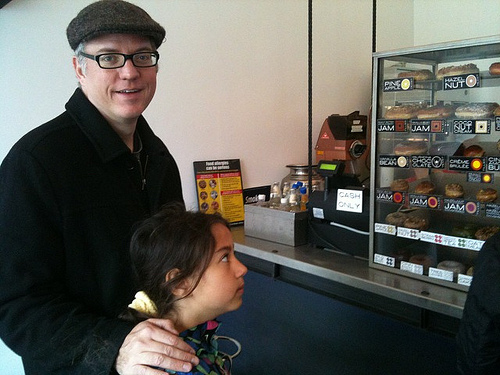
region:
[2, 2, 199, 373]
a man with a girl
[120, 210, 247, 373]
a little girl with black hair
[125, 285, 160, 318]
a yellow scrunchie in a girl's hair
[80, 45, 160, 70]
glasses on a man's face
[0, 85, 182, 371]
a black jacket on a man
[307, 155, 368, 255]
a cash register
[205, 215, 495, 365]
a metal counter top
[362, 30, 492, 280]
a pastry display case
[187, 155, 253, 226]
a sign on a counter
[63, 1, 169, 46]
a hat on a man's head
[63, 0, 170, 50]
Hat worn by the man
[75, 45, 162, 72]
Glasses on the man's face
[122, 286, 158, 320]
Yellow hair tie in the girl's hair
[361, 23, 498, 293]
Display case with pastries inside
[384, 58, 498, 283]
Pastries in the display case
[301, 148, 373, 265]
The black cash register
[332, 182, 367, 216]
The white 'cash only' sign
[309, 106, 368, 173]
The brown coffee grinder behind cash register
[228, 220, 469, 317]
The metal shelf in front of display case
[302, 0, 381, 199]
The two black lines on the wall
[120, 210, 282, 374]
girl looking at food display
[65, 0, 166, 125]
man with dark glasses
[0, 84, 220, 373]
sweatshirt with long sleeves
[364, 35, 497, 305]
a display of donuts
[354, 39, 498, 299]
a display of doughnuts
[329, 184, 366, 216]
a business that is cash only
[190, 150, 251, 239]
promotional sign against the wall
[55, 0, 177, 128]
man wearing a hat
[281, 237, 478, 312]
a metallic counter top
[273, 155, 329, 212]
a glass jar on the counter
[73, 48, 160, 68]
a man's eyeglasses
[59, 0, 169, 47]
a man's black hat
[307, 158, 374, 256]
a black cash register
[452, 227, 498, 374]
the arm of a person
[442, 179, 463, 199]
a brown doughnut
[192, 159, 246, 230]
a brown, red and yellow sign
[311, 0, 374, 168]
part of a white wall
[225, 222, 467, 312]
a silver counter top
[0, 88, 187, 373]
a man's black jacket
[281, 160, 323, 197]
a large silver vase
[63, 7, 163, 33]
Man wears dark grey hat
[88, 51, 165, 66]
Man is wearing glasses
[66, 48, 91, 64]
Man has grey hair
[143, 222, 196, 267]
Little girl has black hair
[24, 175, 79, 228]
Man wearing black coat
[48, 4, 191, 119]
Man has smile on his face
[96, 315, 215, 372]
Mans hand is on girls shoulder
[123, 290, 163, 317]
Yellow ponytail in girls hair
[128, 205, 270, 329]
Girl looking at counter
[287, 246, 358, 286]
Silver counter in store